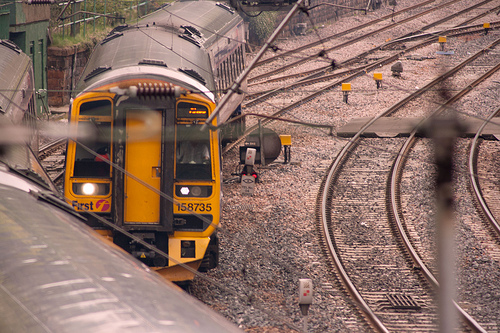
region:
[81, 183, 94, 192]
Front light of train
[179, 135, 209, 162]
The train driver seated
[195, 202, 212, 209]
Numbers in the front of train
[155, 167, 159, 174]
The handle on the door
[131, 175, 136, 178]
A overhanging calbe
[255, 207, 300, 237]
Gravel on the truck surface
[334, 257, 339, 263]
A train track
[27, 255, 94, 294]
The roof of a train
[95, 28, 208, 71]
roof of the train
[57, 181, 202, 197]
lights on the train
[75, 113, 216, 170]
windsheild on the train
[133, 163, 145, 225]
the train is yellow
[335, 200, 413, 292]
track for the train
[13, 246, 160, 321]
top of the train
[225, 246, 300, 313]
stones on the ground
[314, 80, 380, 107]
pole on the ground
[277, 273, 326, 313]
pole on the ground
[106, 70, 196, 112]
black part of train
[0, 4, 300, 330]
two traims are in the picture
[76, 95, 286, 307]
train head is yellow in color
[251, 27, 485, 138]
the bumps are aranged in order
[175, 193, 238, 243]
numbers are written in black color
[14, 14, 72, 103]
the hut is next to the train ways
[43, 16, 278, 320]
the train is at a stop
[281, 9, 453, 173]
the bumps are yellow in color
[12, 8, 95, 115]
the hut is made of metals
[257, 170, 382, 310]
the floor is made of rocks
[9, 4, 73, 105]
the hutr is green in color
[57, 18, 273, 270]
train running on the track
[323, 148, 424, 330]
railway track made with metal rod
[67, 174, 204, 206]
head light of the train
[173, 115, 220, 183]
front glass with wipers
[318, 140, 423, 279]
crushed stone alongside railroad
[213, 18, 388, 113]
electric cables in the railway station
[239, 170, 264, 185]
indicator light between tracks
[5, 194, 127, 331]
train parked in the railway station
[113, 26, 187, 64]
top of the train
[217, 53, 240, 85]
side window of the train